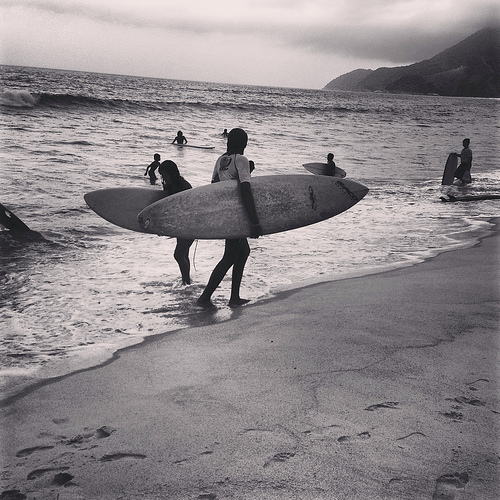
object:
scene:
[0, 0, 499, 499]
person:
[194, 125, 266, 314]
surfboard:
[439, 149, 460, 188]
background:
[0, 1, 499, 499]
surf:
[137, 128, 371, 314]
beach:
[0, 231, 499, 499]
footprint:
[430, 469, 472, 499]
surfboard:
[136, 172, 370, 241]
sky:
[0, 1, 499, 90]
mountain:
[319, 25, 499, 96]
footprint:
[334, 430, 372, 446]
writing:
[334, 177, 359, 205]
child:
[143, 153, 161, 187]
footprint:
[258, 448, 296, 473]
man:
[452, 137, 474, 184]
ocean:
[0, 64, 499, 406]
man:
[170, 129, 187, 150]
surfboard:
[169, 141, 216, 149]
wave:
[0, 84, 394, 116]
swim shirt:
[213, 150, 250, 184]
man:
[321, 151, 334, 173]